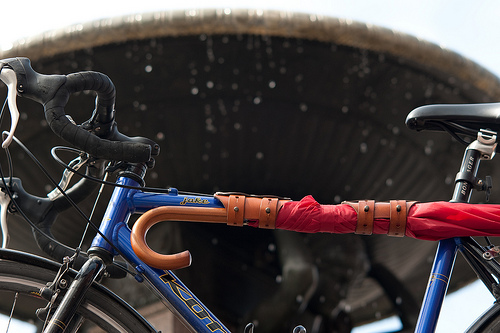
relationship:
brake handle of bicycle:
[0, 64, 22, 150] [0, 56, 498, 332]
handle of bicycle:
[3, 55, 158, 180] [0, 56, 498, 332]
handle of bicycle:
[0, 55, 162, 281] [0, 56, 498, 332]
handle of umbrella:
[0, 55, 162, 281] [112, 152, 475, 299]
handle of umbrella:
[129, 206, 223, 266] [130, 195, 499, 272]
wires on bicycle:
[16, 139, 133, 289] [0, 55, 499, 331]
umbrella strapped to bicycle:
[127, 194, 496, 278] [0, 56, 498, 332]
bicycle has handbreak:
[0, 56, 498, 332] [0, 62, 28, 150]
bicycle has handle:
[0, 56, 498, 332] [25, 54, 161, 209]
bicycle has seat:
[0, 56, 498, 332] [405, 101, 497, 138]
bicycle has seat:
[0, 55, 499, 331] [401, 95, 495, 129]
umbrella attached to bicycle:
[130, 195, 499, 272] [0, 55, 499, 331]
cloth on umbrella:
[281, 199, 498, 235] [119, 180, 499, 286]